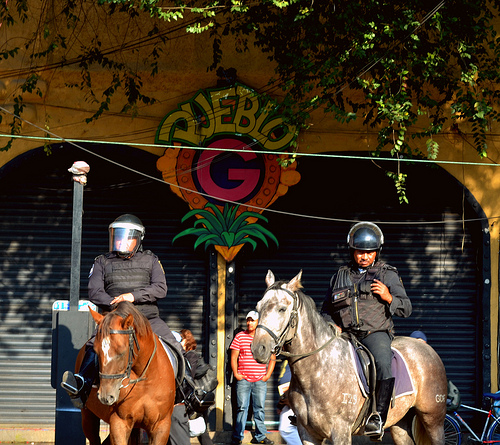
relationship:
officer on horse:
[327, 217, 418, 444] [251, 267, 454, 444]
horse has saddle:
[251, 267, 454, 444] [344, 333, 419, 402]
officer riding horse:
[327, 217, 418, 444] [251, 267, 454, 444]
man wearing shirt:
[225, 304, 281, 444] [229, 327, 274, 385]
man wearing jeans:
[225, 304, 281, 444] [234, 376, 269, 442]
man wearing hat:
[225, 304, 281, 444] [245, 309, 260, 321]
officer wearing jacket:
[327, 217, 418, 444] [319, 259, 416, 339]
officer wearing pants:
[327, 217, 418, 444] [342, 324, 399, 414]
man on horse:
[53, 207, 213, 420] [68, 304, 193, 444]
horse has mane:
[68, 304, 193, 444] [96, 298, 148, 345]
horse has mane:
[251, 267, 454, 444] [268, 276, 333, 343]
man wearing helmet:
[53, 207, 213, 420] [104, 212, 147, 259]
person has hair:
[161, 326, 221, 445] [176, 327, 204, 354]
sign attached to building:
[145, 77, 303, 220] [3, 0, 500, 427]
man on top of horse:
[53, 207, 213, 420] [68, 304, 193, 444]